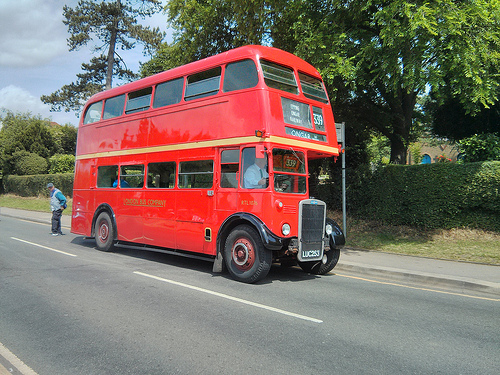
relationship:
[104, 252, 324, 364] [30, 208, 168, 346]
line on road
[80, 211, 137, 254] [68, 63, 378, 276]
tire on bus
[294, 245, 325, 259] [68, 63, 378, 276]
plate on bus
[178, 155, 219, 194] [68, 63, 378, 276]
window on bus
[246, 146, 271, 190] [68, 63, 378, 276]
driver of bus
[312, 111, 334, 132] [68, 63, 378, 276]
number on bus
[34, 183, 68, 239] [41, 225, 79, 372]
man on street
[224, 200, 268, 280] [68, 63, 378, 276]
wheel of bus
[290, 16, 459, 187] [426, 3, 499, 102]
tree with leaves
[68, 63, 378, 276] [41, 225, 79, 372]
bus on street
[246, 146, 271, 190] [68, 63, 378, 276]
driver on bus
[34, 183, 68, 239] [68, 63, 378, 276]
man behind bus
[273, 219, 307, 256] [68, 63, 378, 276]
headlight on bus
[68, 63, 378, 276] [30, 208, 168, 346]
bus on road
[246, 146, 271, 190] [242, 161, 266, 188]
driver wearing shirt